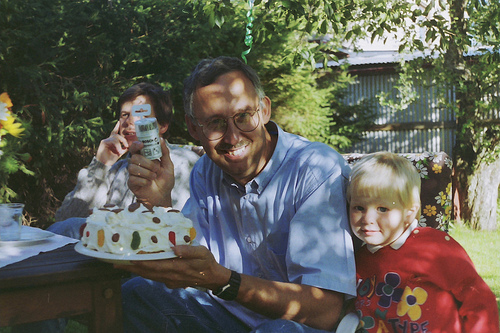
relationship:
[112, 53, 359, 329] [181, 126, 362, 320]
man wearing shirt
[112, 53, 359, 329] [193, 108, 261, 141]
man wearing eyeglasses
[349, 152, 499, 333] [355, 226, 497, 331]
baby wearing red shirt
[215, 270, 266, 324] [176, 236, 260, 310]
watch on wrist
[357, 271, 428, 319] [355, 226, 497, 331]
flowers on red shirt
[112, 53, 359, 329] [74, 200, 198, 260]
man holding cake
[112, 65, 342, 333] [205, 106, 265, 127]
man wearing eyeglasses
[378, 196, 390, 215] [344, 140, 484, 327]
eye of baby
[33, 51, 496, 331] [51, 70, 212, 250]
people sitting with people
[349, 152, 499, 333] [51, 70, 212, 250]
baby sitting with people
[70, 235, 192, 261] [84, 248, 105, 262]
plate has part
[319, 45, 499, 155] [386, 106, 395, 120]
steel has part